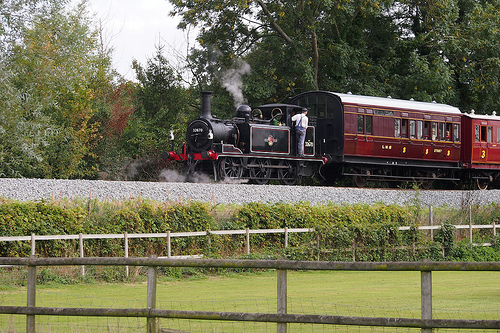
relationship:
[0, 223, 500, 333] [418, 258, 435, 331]
fence with wooden post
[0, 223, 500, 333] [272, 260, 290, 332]
fence with wooden post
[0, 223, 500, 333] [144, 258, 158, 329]
fence with wooden post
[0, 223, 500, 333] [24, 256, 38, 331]
fence with wooden post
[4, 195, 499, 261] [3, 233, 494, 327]
foliage along fence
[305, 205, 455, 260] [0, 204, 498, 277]
plants growing on fence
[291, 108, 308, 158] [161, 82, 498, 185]
engineer on side on train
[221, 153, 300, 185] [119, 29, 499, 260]
wheels are on train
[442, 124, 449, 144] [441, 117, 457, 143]
person looking out window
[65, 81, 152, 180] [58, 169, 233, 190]
trees growing by track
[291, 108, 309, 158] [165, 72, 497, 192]
conductor outside of train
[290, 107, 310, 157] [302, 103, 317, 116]
conductor wearing hat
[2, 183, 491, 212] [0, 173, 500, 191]
rocks along track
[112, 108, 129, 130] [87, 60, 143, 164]
leaves on tree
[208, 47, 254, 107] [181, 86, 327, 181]
smoke coming from engine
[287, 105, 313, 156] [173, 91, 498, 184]
engineer on train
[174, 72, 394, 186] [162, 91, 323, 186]
front on engine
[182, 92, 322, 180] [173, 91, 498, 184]
engine on train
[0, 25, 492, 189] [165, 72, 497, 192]
trees by train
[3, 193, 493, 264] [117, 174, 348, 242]
weeds growing bank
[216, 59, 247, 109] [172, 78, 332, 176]
smoke coming from engine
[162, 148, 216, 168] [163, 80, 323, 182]
guard on engine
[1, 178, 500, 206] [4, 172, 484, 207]
gravel on bed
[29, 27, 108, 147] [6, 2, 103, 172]
yellow leaves on tree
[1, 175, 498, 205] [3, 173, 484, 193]
gravel next to track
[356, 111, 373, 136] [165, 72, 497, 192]
windows on train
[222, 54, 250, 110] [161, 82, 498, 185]
steam from train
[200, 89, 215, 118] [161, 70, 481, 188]
stack on train